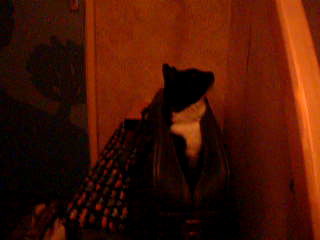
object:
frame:
[81, 0, 94, 170]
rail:
[268, 0, 320, 240]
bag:
[127, 87, 232, 238]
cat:
[161, 62, 216, 168]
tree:
[24, 34, 85, 122]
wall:
[0, 0, 83, 130]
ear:
[162, 62, 175, 81]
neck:
[165, 95, 207, 123]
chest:
[167, 120, 203, 164]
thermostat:
[67, 0, 81, 12]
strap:
[141, 107, 149, 121]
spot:
[1, 0, 16, 48]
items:
[33, 204, 47, 216]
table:
[0, 210, 44, 239]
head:
[161, 57, 214, 110]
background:
[0, 16, 113, 146]